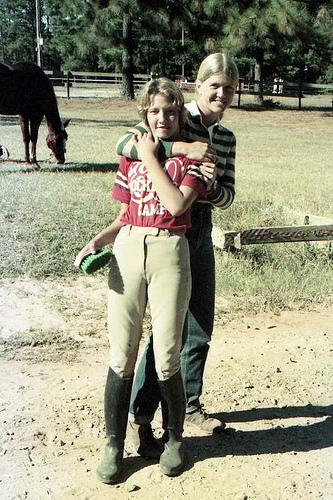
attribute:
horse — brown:
[2, 52, 72, 167]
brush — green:
[71, 248, 112, 275]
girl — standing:
[118, 51, 236, 456]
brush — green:
[59, 246, 110, 276]